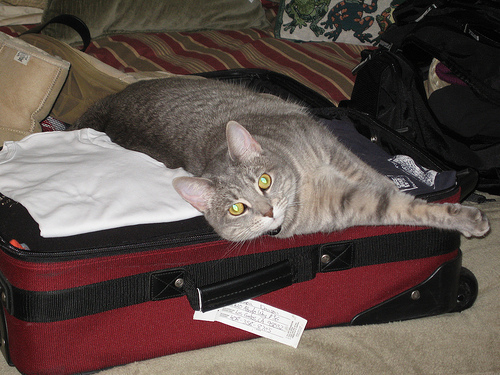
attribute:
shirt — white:
[11, 116, 144, 246]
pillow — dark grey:
[118, 6, 265, 46]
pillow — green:
[287, 4, 395, 55]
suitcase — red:
[7, 146, 479, 373]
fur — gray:
[97, 70, 490, 244]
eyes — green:
[231, 175, 274, 220]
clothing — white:
[317, 116, 472, 190]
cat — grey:
[88, 77, 455, 233]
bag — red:
[4, 211, 464, 336]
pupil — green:
[254, 171, 277, 194]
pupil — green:
[226, 201, 247, 220]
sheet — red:
[80, 24, 362, 105]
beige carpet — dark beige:
[353, 310, 452, 370]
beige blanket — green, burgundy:
[220, 345, 389, 370]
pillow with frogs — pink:
[278, 0, 398, 48]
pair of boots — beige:
[2, 28, 136, 146]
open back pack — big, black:
[351, 0, 497, 184]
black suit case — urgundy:
[8, 171, 466, 361]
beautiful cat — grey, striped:
[96, 66, 495, 273]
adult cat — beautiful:
[62, 70, 480, 279]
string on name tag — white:
[192, 285, 211, 318]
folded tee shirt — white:
[2, 133, 205, 239]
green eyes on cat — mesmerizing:
[208, 170, 283, 223]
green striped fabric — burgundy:
[165, 30, 255, 63]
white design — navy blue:
[384, 169, 417, 195]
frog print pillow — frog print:
[285, 1, 384, 57]